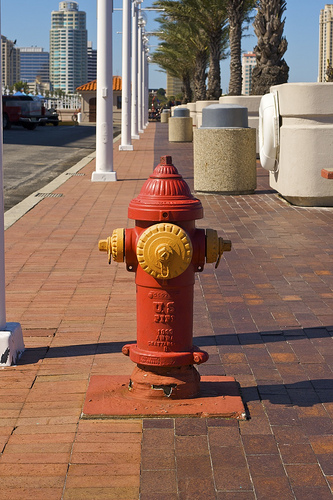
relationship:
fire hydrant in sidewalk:
[80, 151, 248, 421] [39, 184, 107, 364]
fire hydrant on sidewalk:
[80, 151, 248, 421] [39, 184, 107, 364]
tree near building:
[166, 7, 276, 97] [41, 6, 90, 87]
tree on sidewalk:
[166, 7, 276, 97] [39, 184, 107, 364]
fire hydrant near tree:
[80, 151, 248, 421] [166, 7, 276, 97]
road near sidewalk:
[26, 121, 79, 180] [39, 184, 107, 364]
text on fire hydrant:
[150, 299, 173, 345] [80, 151, 248, 421]